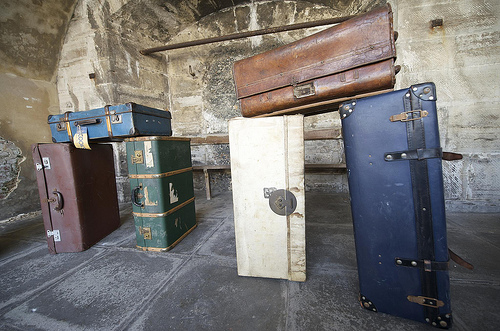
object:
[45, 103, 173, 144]
suitcase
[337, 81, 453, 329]
suitcase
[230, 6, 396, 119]
suitcase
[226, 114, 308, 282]
suitcase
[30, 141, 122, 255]
suitcase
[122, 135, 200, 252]
suitcase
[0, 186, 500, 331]
floor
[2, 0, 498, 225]
wall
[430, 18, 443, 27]
rust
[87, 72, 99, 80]
rust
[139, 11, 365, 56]
bar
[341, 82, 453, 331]
suitcases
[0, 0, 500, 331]
cave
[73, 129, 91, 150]
tag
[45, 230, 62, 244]
locks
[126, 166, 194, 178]
gold trim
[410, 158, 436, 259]
black straps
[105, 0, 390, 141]
alcove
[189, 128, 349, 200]
bench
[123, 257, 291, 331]
panels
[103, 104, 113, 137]
straps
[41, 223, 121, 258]
side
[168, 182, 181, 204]
labels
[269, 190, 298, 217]
latch